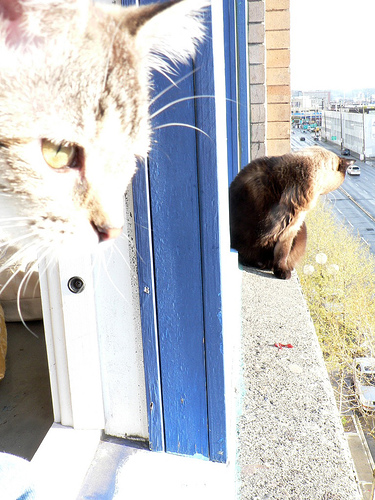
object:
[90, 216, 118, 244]
nose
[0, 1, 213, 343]
cat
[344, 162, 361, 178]
car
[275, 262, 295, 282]
paw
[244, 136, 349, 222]
cat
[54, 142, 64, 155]
pupil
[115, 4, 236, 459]
paint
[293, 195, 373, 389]
grass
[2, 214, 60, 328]
whiskers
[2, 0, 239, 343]
eye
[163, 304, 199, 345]
blue